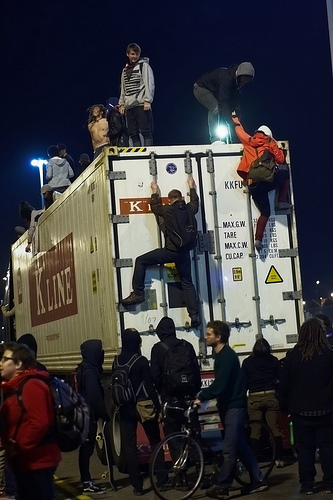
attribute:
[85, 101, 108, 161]
person — shirtless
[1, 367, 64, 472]
jacket — red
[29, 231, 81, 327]
logo — red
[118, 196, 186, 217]
logo — red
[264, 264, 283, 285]
hazard label — yellow, black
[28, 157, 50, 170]
light — illuminated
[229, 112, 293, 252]
man — young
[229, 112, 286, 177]
jacket — red, orange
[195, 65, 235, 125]
jacket — gray, black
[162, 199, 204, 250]
backpack — black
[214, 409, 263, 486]
jeans — black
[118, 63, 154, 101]
shirt — gray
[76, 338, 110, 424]
jacket — dark